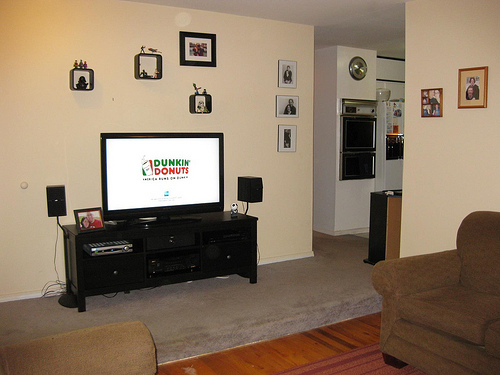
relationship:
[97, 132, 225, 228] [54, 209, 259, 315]
television on stand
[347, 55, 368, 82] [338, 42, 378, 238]
clock on wall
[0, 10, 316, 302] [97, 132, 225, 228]
wall behind television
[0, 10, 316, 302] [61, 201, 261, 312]
wall behind stand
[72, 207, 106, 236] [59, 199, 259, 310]
photographs on tv stand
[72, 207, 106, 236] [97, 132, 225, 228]
photographs next to television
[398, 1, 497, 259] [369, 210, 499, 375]
wall behind a chairs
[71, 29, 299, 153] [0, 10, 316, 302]
frames on a wall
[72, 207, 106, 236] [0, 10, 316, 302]
photographs on a wall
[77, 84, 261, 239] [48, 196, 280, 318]
television on entertainment stant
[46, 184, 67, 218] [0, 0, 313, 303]
speaker on wall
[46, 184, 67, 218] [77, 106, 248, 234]
speaker near television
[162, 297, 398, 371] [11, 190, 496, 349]
floor by chairs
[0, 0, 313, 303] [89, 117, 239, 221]
wall behind television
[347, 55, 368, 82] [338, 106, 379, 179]
clock hanging above oven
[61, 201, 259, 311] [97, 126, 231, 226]
entertainment center under tv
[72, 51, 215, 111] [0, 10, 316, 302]
shelves are hanging on wall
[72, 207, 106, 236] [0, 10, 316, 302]
photographs are hanging on wall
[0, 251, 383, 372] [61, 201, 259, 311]
carpet under entertainment center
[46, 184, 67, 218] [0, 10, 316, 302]
speaker are hanging on a wall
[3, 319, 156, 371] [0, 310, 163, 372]
arm from sofa chair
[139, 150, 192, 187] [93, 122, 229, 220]
advertisement from tv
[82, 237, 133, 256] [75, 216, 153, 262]
box on shelf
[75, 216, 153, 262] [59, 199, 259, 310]
shelf on tv stand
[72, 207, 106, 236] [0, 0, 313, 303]
photographs on wall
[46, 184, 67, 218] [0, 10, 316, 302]
speaker mounted on wall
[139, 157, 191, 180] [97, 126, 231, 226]
advertisement on tv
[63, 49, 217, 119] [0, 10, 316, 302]
shelves are hanging on wall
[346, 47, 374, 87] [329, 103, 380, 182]
clock above oven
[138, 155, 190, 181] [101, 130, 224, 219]
dunkin' donuts on screen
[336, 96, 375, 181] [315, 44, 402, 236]
oven at entrance to kitchen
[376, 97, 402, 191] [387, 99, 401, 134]
refrigerator has magnets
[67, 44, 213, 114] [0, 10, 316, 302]
bric-a-brack hanging on wall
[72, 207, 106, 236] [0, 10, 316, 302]
photographs hanging on wall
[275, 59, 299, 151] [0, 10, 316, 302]
photographs hanging on wall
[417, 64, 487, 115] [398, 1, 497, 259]
photographs hanging on wall